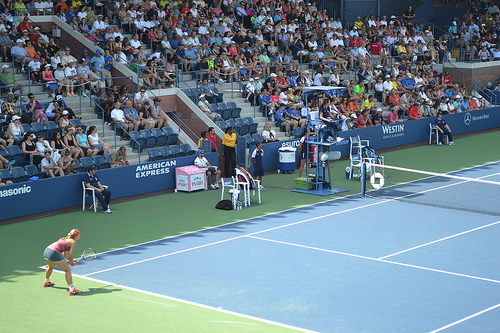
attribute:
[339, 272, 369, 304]
part — of a court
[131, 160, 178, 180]
american express — the sponsor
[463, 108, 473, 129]
mercedes logo — on the wall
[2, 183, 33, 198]
panasonic — advertised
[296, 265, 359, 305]
part — of a court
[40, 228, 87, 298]
girl — bending over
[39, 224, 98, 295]
girl — holding a racket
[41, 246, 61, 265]
blue skirt — short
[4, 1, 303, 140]
people — sitting in the stands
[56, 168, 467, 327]
tennis court — blue with white stripes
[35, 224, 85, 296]
woman —  playing tennis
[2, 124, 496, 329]
court — large , green 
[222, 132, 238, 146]
shirt — yellow 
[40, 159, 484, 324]
court — blue, white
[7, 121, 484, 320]
trim — green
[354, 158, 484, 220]
net — white, black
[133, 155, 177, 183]
writing — white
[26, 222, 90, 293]
player — TENNIS, PINK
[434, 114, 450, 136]
man — BLUE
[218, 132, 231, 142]
shirt — YELLOW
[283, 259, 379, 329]
court — BLUE, PART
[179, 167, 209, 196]
container — water container, evian water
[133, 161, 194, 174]
text — american express, wall text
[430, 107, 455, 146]
man — sitting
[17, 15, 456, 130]
people — sitting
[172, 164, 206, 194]
box — pink, white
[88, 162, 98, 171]
hat — blue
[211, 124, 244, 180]
woman — standing